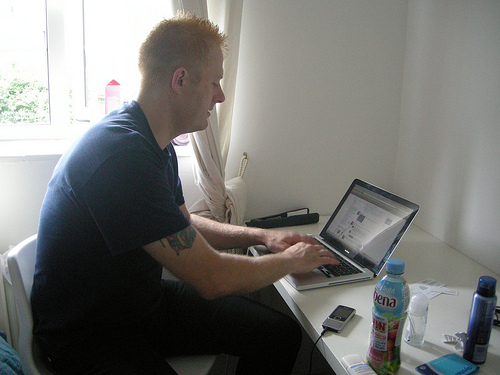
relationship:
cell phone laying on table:
[321, 301, 355, 336] [239, 213, 499, 373]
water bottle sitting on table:
[367, 256, 411, 374] [239, 213, 499, 373]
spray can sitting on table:
[460, 275, 497, 365] [239, 213, 499, 373]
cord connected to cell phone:
[306, 326, 328, 375] [321, 301, 355, 336]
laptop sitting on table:
[269, 177, 420, 292] [239, 213, 499, 373]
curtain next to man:
[169, 1, 252, 228] [30, 10, 340, 373]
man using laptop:
[30, 10, 340, 373] [269, 177, 420, 292]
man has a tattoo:
[30, 10, 340, 373] [158, 226, 196, 258]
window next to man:
[0, 0, 192, 150] [30, 10, 340, 373]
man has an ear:
[30, 10, 340, 373] [168, 66, 189, 97]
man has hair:
[30, 10, 340, 373] [137, 14, 229, 73]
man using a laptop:
[30, 10, 340, 373] [269, 177, 420, 292]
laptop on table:
[269, 177, 420, 292] [239, 213, 499, 373]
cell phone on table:
[321, 301, 355, 336] [239, 213, 499, 373]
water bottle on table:
[367, 256, 411, 374] [239, 213, 499, 373]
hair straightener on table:
[248, 205, 320, 227] [239, 213, 499, 373]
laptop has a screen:
[269, 177, 420, 292] [317, 179, 419, 277]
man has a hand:
[30, 10, 340, 373] [284, 242, 343, 274]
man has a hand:
[30, 10, 340, 373] [262, 230, 319, 254]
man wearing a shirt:
[30, 10, 340, 373] [29, 97, 191, 335]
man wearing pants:
[30, 10, 340, 373] [28, 278, 302, 373]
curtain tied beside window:
[169, 1, 252, 228] [0, 0, 192, 150]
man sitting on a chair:
[30, 10, 340, 373] [5, 231, 220, 375]